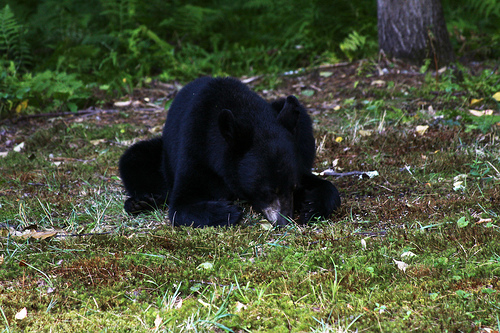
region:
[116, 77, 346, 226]
A black bear sleeping.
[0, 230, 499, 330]
A patch of grass and weeds.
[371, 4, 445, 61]
The bottom part of a tree trunk.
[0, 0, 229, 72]
Green foliage in the background.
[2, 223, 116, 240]
A fallen branch with leaves.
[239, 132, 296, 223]
The black bear's head.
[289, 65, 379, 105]
A patch of dirt and fallen leaves.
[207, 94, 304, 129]
The black bear's ears.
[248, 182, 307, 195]
The two eyes of the bear.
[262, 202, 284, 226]
The bear's nose to the ground.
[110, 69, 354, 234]
A bear laying down on the ground in the woods.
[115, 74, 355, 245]
The bear is black.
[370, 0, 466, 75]
base of a tree behind the bear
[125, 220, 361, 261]
grass the bear is laying on.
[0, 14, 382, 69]
ferns and other green under brush of the woods.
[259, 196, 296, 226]
muzzle of the black bear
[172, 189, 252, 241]
left front paw of the black bear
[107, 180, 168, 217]
left hind paw of the black bear.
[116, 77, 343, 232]
The bear appears to be asleep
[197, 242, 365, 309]
Green grass in the clearing of the woods.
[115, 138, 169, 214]
the black leg of the bear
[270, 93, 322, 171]
the black leg of the bear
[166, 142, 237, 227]
the black leg of the bear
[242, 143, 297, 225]
the black head of the bear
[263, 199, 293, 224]
the brown snout of the bear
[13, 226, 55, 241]
a light brown leaf on the ground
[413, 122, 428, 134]
a light brown leaf on the ground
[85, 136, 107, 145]
a light brown leaf on the ground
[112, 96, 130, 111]
a light brown leaf on the ground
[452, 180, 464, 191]
a light brown leaf on the ground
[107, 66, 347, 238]
A black bear in grass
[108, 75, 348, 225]
Bear laying down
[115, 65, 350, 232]
Bear is laying down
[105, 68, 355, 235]
Black bear laying down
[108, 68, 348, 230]
Black bear is laying down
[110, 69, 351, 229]
Bear on the grass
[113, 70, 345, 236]
Bear is on the grass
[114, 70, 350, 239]
Bear laying on the grass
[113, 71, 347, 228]
Bear is laying on the grass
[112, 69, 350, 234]
Bear sleeping on the grass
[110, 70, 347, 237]
Bear is sleeping on the grass